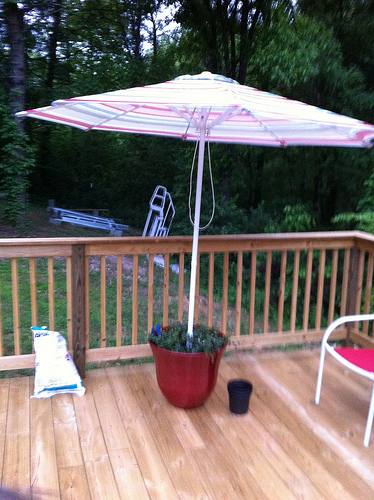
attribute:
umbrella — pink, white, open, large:
[11, 67, 374, 150]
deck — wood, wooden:
[0, 346, 373, 498]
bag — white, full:
[30, 322, 87, 401]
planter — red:
[149, 326, 230, 410]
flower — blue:
[154, 322, 166, 334]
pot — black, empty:
[227, 377, 253, 417]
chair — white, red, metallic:
[312, 312, 374, 449]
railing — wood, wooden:
[0, 227, 373, 371]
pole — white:
[55, 205, 125, 233]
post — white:
[186, 131, 206, 338]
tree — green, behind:
[250, 4, 364, 229]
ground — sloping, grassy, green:
[0, 203, 345, 373]